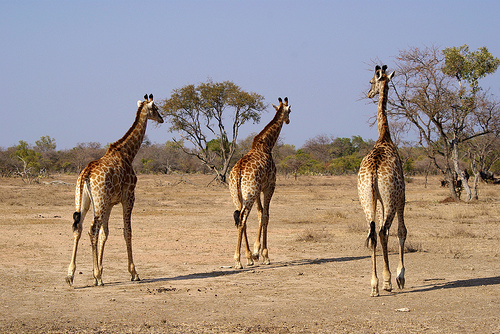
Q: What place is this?
A: It is a field.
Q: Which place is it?
A: It is a field.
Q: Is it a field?
A: Yes, it is a field.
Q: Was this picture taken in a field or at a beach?
A: It was taken at a field.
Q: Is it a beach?
A: No, it is a field.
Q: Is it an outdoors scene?
A: Yes, it is outdoors.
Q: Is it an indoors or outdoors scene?
A: It is outdoors.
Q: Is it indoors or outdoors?
A: It is outdoors.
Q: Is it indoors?
A: No, it is outdoors.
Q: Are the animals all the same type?
A: Yes, all the animals are giraffes.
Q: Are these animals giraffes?
A: Yes, all the animals are giraffes.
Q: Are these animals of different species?
A: No, all the animals are giraffes.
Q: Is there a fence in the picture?
A: No, there are no fences.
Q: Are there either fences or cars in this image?
A: No, there are no fences or cars.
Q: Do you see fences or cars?
A: No, there are no fences or cars.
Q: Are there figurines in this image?
A: No, there are no figurines.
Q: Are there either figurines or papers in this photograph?
A: No, there are no figurines or papers.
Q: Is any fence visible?
A: No, there are no fences.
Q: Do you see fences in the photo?
A: No, there are no fences.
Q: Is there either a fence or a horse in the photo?
A: No, there are no fences or horses.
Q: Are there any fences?
A: No, there are no fences.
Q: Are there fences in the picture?
A: No, there are no fences.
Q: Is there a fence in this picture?
A: No, there are no fences.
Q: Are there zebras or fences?
A: No, there are no fences or zebras.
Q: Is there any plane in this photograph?
A: No, there are no airplanes.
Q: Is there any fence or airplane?
A: No, there are no airplanes or fences.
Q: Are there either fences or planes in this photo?
A: No, there are no planes or fences.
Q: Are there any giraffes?
A: Yes, there is a giraffe.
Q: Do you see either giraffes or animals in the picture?
A: Yes, there is a giraffe.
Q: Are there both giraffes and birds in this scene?
A: No, there is a giraffe but no birds.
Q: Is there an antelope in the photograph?
A: No, there are no antelopes.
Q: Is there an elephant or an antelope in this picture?
A: No, there are no antelopes or elephants.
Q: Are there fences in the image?
A: No, there are no fences.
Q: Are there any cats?
A: No, there are no cats.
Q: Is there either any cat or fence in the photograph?
A: No, there are no cats or fences.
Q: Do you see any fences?
A: No, there are no fences.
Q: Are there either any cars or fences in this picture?
A: No, there are no fences or cars.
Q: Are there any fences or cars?
A: No, there are no fences or cars.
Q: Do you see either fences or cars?
A: No, there are no fences or cars.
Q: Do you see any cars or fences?
A: No, there are no fences or cars.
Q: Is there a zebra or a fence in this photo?
A: No, there are no fences or zebras.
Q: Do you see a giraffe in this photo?
A: Yes, there is a giraffe.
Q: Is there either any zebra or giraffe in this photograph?
A: Yes, there is a giraffe.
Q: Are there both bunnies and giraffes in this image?
A: No, there is a giraffe but no bunnies.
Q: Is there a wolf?
A: No, there are no wolves.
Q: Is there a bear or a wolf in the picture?
A: No, there are no wolves or bears.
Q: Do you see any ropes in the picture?
A: No, there are no ropes.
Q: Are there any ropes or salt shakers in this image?
A: No, there are no ropes or salt shakers.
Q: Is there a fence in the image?
A: No, there are no fences.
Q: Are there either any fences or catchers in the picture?
A: No, there are no fences or catchers.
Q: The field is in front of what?
A: The field is in front of the shrubs.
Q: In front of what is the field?
A: The field is in front of the shrubs.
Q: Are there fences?
A: No, there are no fences.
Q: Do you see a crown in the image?
A: No, there are no crowns.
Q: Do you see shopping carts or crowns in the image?
A: No, there are no crowns or shopping carts.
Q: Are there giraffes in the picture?
A: Yes, there is a giraffe.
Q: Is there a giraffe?
A: Yes, there is a giraffe.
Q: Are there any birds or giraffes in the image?
A: Yes, there is a giraffe.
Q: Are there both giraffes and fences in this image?
A: No, there is a giraffe but no fences.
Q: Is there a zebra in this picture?
A: No, there are no zebras.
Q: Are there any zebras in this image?
A: No, there are no zebras.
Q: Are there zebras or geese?
A: No, there are no zebras or geese.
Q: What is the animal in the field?
A: The animal is a giraffe.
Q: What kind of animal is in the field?
A: The animal is a giraffe.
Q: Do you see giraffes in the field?
A: Yes, there is a giraffe in the field.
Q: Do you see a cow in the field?
A: No, there is a giraffe in the field.